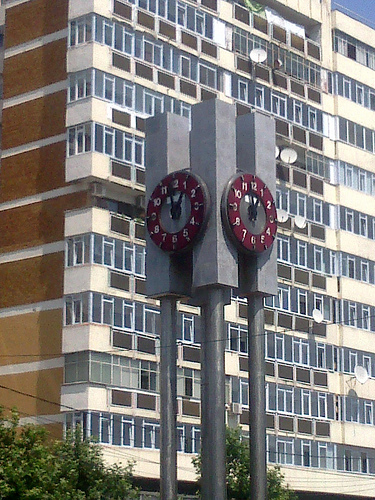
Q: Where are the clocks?
A: In front of the building.